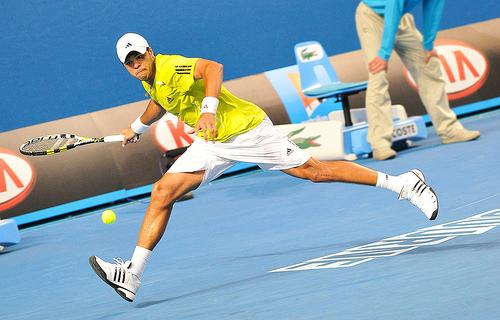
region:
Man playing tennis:
[87, 31, 438, 304]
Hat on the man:
[115, 32, 150, 64]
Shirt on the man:
[141, 54, 266, 144]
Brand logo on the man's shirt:
[163, 95, 175, 105]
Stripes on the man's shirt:
[171, 64, 194, 75]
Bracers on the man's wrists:
[130, 97, 218, 135]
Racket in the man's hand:
[18, 132, 138, 155]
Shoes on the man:
[88, 168, 439, 303]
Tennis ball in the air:
[99, 208, 117, 226]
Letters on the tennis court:
[271, 208, 499, 272]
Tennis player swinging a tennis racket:
[14, 34, 443, 264]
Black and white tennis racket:
[17, 129, 131, 156]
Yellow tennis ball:
[102, 208, 114, 223]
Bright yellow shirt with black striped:
[155, 51, 259, 137]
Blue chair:
[290, 37, 362, 132]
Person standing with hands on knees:
[351, 3, 487, 158]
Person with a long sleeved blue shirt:
[360, 0, 447, 68]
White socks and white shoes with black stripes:
[373, 168, 440, 220]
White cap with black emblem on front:
[116, 32, 148, 61]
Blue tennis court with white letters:
[265, 224, 495, 302]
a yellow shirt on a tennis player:
[142, 53, 263, 147]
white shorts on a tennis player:
[167, 114, 308, 192]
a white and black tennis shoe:
[86, 252, 140, 302]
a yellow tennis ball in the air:
[101, 206, 117, 224]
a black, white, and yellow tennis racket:
[17, 132, 139, 157]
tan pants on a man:
[353, 2, 463, 148]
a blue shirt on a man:
[369, 1, 447, 56]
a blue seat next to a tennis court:
[290, 39, 370, 127]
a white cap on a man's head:
[112, 30, 150, 62]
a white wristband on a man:
[196, 95, 220, 116]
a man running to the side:
[18, 30, 440, 304]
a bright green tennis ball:
[100, 205, 116, 225]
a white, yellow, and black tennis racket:
[18, 132, 120, 153]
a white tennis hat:
[115, 28, 147, 63]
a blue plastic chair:
[292, 39, 371, 99]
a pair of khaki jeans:
[355, 2, 467, 149]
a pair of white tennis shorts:
[166, 115, 312, 191]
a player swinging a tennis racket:
[20, 31, 440, 302]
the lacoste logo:
[285, 120, 319, 150]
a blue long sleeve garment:
[364, 0, 446, 57]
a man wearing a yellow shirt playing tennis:
[18, 23, 440, 303]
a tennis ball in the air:
[98, 204, 118, 229]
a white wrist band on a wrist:
[197, 94, 224, 114]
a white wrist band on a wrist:
[128, 113, 152, 136]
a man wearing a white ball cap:
[111, 25, 226, 134]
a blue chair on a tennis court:
[291, 34, 371, 153]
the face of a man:
[124, 52, 154, 81]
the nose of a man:
[131, 53, 142, 71]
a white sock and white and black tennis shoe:
[375, 168, 443, 218]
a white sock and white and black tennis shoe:
[86, 241, 154, 305]